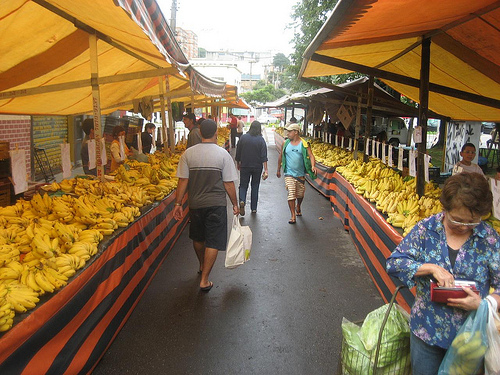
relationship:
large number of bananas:
[0, 134, 414, 332] [2, 149, 176, 327]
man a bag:
[171, 119, 243, 289] [222, 211, 255, 272]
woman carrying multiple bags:
[382, 170, 498, 373] [338, 281, 498, 374]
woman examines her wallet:
[382, 170, 498, 373] [429, 276, 480, 310]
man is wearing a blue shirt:
[276, 124, 321, 228] [276, 138, 314, 175]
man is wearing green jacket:
[276, 124, 321, 228] [300, 139, 315, 180]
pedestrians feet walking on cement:
[286, 202, 304, 227] [112, 147, 381, 369]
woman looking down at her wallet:
[382, 170, 498, 373] [429, 276, 480, 310]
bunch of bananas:
[395, 197, 422, 219] [316, 140, 438, 218]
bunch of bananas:
[330, 149, 408, 230] [2, 149, 176, 327]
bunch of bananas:
[330, 149, 408, 230] [316, 140, 438, 218]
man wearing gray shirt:
[171, 119, 243, 289] [174, 139, 239, 211]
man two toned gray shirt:
[171, 119, 243, 289] [174, 139, 239, 211]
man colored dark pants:
[171, 119, 243, 289] [188, 207, 230, 253]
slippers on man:
[286, 202, 304, 227] [276, 124, 321, 228]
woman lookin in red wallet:
[382, 170, 498, 373] [429, 276, 480, 310]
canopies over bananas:
[2, 2, 498, 121] [2, 149, 176, 327]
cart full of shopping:
[338, 283, 410, 374] [338, 281, 498, 374]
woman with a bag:
[382, 170, 498, 373] [438, 301, 487, 373]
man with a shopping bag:
[171, 119, 243, 289] [222, 211, 255, 272]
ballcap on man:
[285, 122, 303, 133] [276, 124, 321, 228]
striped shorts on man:
[284, 176, 307, 202] [276, 124, 321, 228]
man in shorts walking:
[276, 124, 321, 228] [286, 175, 310, 227]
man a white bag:
[171, 119, 243, 289] [222, 211, 255, 272]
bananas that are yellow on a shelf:
[2, 149, 176, 327] [316, 140, 438, 218]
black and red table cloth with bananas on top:
[317, 173, 405, 301] [316, 140, 438, 218]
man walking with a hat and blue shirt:
[276, 124, 321, 228] [281, 121, 308, 176]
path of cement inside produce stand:
[112, 147, 381, 369] [0, 1, 500, 369]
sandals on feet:
[196, 268, 215, 295] [196, 268, 212, 288]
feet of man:
[196, 268, 212, 288] [171, 119, 243, 288]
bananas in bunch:
[22, 234, 83, 283] [330, 149, 408, 230]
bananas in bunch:
[72, 186, 108, 233] [2, 149, 176, 327]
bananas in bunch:
[112, 175, 152, 198] [26, 263, 67, 292]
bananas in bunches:
[17, 184, 51, 224] [2, 149, 176, 327]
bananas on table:
[2, 149, 176, 327] [15, 184, 162, 373]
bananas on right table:
[352, 154, 404, 188] [316, 140, 438, 218]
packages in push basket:
[333, 284, 407, 371] [338, 283, 410, 374]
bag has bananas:
[430, 294, 497, 372] [452, 319, 490, 366]